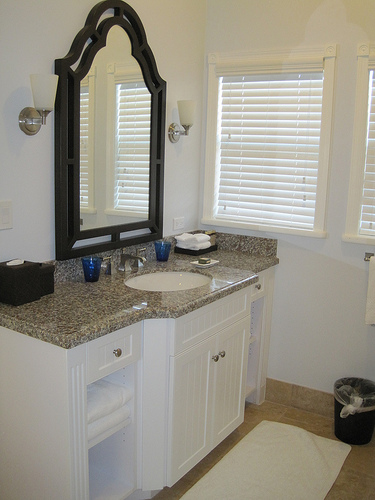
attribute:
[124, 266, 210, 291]
sink — white, round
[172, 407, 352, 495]
rug — white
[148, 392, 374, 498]
floor — brown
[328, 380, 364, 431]
can — black, short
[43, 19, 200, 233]
mirror — black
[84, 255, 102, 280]
glass cup — blue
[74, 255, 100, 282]
cup — blue, glass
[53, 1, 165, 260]
mirror — black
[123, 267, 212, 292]
sink — white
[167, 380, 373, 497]
floor —  brown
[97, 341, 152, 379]
handle — small, brass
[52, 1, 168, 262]
mirror. — black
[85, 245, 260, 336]
bathroom vanity — marble-topped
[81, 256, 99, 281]
glass — blue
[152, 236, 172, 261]
glass — blue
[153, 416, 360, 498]
mat — rectangular, white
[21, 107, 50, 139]
sconses — silver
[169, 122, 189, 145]
sconses — silver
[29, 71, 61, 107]
fixture — white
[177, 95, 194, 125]
fixture — white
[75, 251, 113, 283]
glass cup — blue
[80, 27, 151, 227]
mirror — wall-mounted, brown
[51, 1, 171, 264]
frame — decorative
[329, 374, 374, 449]
wastebasket — black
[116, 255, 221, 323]
sink — white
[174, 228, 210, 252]
towels — folded, white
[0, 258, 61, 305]
holder — brown, square, short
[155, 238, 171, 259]
cup — blue, glass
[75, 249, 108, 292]
cup — blue, glass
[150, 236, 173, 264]
cup — blue, glass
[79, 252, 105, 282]
cup — glass, blue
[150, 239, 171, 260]
cup — glass, blue